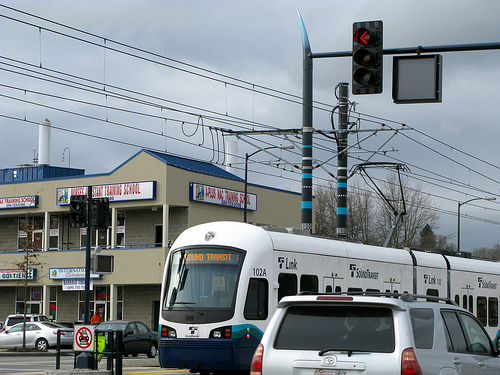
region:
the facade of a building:
[2, 177, 163, 352]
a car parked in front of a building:
[79, 316, 157, 365]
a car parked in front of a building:
[3, 314, 76, 364]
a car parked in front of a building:
[3, 307, 45, 334]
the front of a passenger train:
[169, 244, 236, 327]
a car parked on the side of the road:
[255, 282, 491, 374]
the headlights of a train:
[162, 323, 224, 340]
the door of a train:
[277, 265, 317, 292]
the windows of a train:
[476, 287, 497, 324]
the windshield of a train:
[168, 249, 244, 311]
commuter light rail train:
[158, 221, 498, 368]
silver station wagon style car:
[249, 293, 496, 372]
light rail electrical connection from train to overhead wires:
[354, 162, 409, 245]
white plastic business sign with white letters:
[189, 183, 256, 209]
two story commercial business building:
[0, 148, 316, 331]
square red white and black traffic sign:
[74, 323, 93, 350]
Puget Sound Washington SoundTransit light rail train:
[157, 220, 449, 372]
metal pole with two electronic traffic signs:
[295, 10, 448, 233]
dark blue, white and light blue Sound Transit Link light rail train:
[157, 222, 498, 373]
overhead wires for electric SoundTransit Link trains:
[0, 3, 497, 226]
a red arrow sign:
[331, 12, 395, 118]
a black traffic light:
[339, 15, 401, 143]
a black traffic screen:
[387, 45, 467, 140]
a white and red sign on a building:
[135, 154, 293, 247]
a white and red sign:
[46, 163, 192, 230]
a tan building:
[7, 140, 285, 368]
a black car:
[71, 304, 174, 374]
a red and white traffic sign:
[64, 319, 100, 351]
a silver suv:
[247, 257, 492, 363]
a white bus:
[139, 188, 498, 363]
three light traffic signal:
[346, 15, 386, 101]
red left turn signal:
[350, 24, 379, 51]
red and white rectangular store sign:
[185, 178, 265, 216]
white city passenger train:
[153, 210, 498, 373]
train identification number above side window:
[250, 263, 270, 281]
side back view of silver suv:
[240, 286, 498, 373]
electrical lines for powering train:
[0, 1, 498, 224]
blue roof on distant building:
[0, 147, 307, 207]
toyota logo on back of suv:
[320, 355, 337, 367]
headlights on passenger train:
[158, 323, 233, 343]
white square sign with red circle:
[67, 320, 99, 355]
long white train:
[153, 209, 495, 371]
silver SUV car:
[248, 292, 498, 372]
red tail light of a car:
[247, 340, 272, 373]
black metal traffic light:
[342, 10, 401, 117]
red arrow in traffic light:
[355, 25, 376, 49]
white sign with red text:
[46, 171, 156, 213]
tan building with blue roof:
[8, 146, 313, 247]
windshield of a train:
[163, 241, 242, 331]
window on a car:
[277, 304, 398, 363]